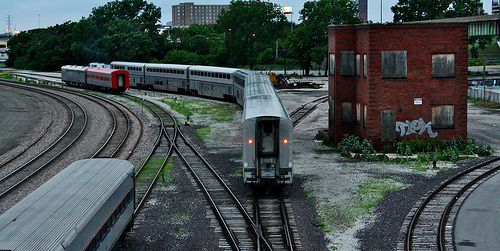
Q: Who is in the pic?
A: No one.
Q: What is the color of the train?
A: Grey.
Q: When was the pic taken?
A: During the day.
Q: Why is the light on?
A: Its getting dark.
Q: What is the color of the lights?
A: Red.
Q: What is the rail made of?
A: Metal.